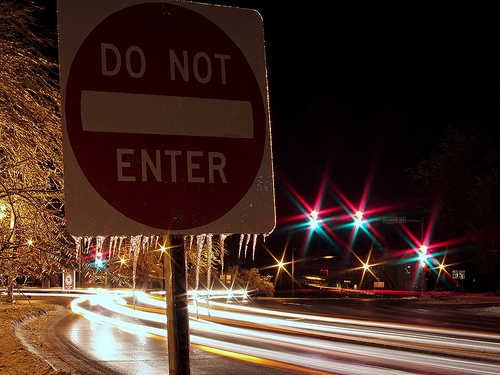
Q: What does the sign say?
A: Do Not Enter.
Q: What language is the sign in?
A: English.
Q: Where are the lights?
A: In background.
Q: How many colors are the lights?
A: 3.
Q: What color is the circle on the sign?
A: Red.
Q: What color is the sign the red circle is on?
A: White.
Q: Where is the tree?
A: Behind the sign.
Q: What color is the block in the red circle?
A: White.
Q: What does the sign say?
A: Do not enter.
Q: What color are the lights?
A: Blue, red and white.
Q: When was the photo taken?
A: Night.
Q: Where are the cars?
A: On road.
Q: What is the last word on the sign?
A: Enter.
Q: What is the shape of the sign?
A: Square.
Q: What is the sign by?
A: Road.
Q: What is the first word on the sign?
A: Do.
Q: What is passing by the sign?
A: Cars.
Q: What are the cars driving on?
A: Road.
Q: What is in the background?
A: Lights.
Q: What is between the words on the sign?
A: White line.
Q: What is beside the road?
A: Grass.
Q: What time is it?
A: Late at night.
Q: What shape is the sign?
A: Square.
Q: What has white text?
A: The sign.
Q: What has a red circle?
A: The sign.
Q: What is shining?
A: Lights.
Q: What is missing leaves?
A: The tree.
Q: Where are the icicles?
A: On the sign.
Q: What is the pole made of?
A: Metal.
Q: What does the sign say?
A: Do not enter.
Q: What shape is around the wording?
A: Circle.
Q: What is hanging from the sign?
A: Icicles.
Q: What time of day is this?
A: Night.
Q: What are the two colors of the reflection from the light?
A: Pink and blue.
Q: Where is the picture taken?
A: On a road.